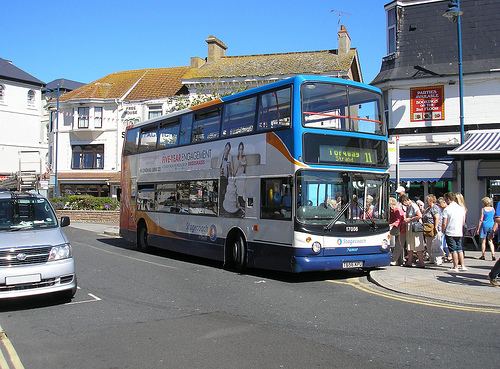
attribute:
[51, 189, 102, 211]
bush — green, large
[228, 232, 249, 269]
tire — black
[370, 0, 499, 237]
building — blue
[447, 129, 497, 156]
awning — white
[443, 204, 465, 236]
shirt — white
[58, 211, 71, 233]
mirror — driver's, side, view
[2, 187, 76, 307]
minivan — gray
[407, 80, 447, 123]
sign — red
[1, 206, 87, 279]
car — parked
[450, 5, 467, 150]
post — light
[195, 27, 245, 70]
chimney — stone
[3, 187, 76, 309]
van — gray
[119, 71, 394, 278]
bus — parked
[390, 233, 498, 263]
stop — bus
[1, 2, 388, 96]
sky — blue